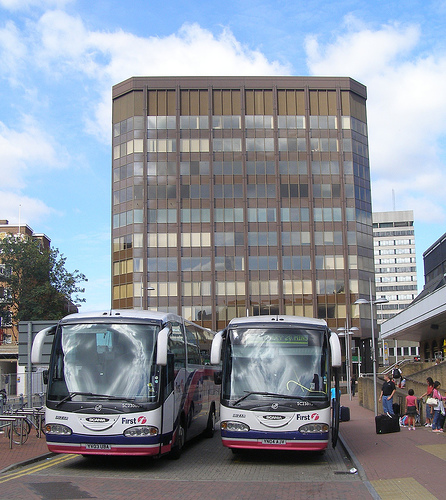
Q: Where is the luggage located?
A: On the ground.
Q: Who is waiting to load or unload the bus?
A: A man and children.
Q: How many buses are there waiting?
A: Two.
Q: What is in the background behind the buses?
A: A building.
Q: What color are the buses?
A: Red, white, and blue.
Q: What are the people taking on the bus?
A: Suitcases.